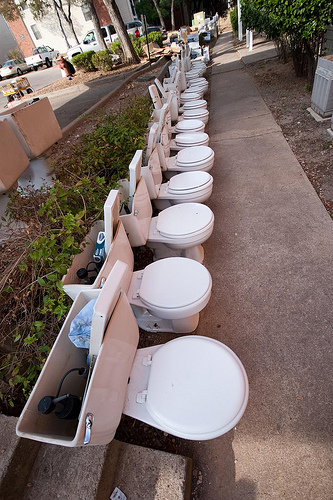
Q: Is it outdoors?
A: Yes, it is outdoors.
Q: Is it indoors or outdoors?
A: It is outdoors.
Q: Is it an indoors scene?
A: No, it is outdoors.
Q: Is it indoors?
A: No, it is outdoors.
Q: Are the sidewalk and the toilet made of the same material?
A: Yes, both the sidewalk and the toilet are made of concrete.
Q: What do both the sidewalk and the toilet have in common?
A: The material, both the sidewalk and the toilet are concrete.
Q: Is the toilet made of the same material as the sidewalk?
A: Yes, both the toilet and the sidewalk are made of concrete.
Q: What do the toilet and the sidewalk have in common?
A: The material, both the toilet and the sidewalk are concrete.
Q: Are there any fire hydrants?
A: Yes, there is a fire hydrant.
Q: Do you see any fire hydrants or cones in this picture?
A: Yes, there is a fire hydrant.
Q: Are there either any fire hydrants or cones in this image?
A: Yes, there is a fire hydrant.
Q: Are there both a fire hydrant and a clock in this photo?
A: No, there is a fire hydrant but no clocks.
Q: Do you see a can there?
A: No, there are no cans.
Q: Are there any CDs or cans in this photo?
A: No, there are no cans or cds.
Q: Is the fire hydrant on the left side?
A: Yes, the fire hydrant is on the left of the image.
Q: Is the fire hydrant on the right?
A: No, the fire hydrant is on the left of the image.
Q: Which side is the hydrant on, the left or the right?
A: The hydrant is on the left of the image.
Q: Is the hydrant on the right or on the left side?
A: The hydrant is on the left of the image.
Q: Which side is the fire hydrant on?
A: The fire hydrant is on the left of the image.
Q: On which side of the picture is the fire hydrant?
A: The fire hydrant is on the left of the image.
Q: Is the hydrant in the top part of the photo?
A: Yes, the hydrant is in the top of the image.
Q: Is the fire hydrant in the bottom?
A: No, the fire hydrant is in the top of the image.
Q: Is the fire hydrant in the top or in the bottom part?
A: The fire hydrant is in the top of the image.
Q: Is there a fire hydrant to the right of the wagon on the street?
A: Yes, there is a fire hydrant to the right of the wagon.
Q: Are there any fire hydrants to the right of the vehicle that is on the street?
A: Yes, there is a fire hydrant to the right of the wagon.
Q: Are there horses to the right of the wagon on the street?
A: No, there is a fire hydrant to the right of the wagon.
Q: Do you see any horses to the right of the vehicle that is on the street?
A: No, there is a fire hydrant to the right of the wagon.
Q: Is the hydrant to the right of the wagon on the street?
A: Yes, the hydrant is to the right of the wagon.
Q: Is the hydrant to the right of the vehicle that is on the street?
A: Yes, the hydrant is to the right of the wagon.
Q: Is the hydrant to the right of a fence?
A: No, the hydrant is to the right of the wagon.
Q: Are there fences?
A: No, there are no fences.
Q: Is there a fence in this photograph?
A: No, there are no fences.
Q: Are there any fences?
A: No, there are no fences.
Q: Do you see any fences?
A: No, there are no fences.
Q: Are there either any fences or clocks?
A: No, there are no fences or clocks.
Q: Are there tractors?
A: No, there are no tractors.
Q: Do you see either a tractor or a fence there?
A: No, there are no tractors or fences.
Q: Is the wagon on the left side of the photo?
A: Yes, the wagon is on the left of the image.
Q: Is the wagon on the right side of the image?
A: No, the wagon is on the left of the image.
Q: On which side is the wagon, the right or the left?
A: The wagon is on the left of the image.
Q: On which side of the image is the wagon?
A: The wagon is on the left of the image.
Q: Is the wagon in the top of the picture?
A: Yes, the wagon is in the top of the image.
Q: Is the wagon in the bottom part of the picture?
A: No, the wagon is in the top of the image.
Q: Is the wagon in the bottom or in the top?
A: The wagon is in the top of the image.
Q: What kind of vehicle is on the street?
A: The vehicle is a wagon.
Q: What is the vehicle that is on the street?
A: The vehicle is a wagon.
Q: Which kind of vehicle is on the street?
A: The vehicle is a wagon.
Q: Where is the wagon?
A: The wagon is on the street.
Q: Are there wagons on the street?
A: Yes, there is a wagon on the street.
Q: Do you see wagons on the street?
A: Yes, there is a wagon on the street.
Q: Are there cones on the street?
A: No, there is a wagon on the street.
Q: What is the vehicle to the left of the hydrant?
A: The vehicle is a wagon.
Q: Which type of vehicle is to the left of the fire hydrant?
A: The vehicle is a wagon.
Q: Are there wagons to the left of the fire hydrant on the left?
A: Yes, there is a wagon to the left of the hydrant.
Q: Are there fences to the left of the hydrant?
A: No, there is a wagon to the left of the hydrant.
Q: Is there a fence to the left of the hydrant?
A: No, there is a wagon to the left of the hydrant.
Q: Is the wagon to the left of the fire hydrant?
A: Yes, the wagon is to the left of the fire hydrant.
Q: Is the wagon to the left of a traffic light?
A: No, the wagon is to the left of the fire hydrant.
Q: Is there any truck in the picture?
A: Yes, there is a truck.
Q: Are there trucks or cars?
A: Yes, there is a truck.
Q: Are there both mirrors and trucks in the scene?
A: No, there is a truck but no mirrors.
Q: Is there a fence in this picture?
A: No, there are no fences.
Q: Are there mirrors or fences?
A: No, there are no fences or mirrors.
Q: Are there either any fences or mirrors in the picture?
A: No, there are no fences or mirrors.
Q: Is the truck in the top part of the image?
A: Yes, the truck is in the top of the image.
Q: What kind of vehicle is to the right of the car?
A: The vehicle is a truck.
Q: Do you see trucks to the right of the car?
A: Yes, there is a truck to the right of the car.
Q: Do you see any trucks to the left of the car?
A: No, the truck is to the right of the car.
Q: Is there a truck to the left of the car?
A: No, the truck is to the right of the car.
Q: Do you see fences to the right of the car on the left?
A: No, there is a truck to the right of the car.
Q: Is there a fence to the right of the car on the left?
A: No, there is a truck to the right of the car.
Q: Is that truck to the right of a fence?
A: No, the truck is to the right of the car.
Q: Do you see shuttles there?
A: No, there are no shuttles.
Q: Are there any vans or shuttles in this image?
A: No, there are no shuttles or vans.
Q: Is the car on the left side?
A: Yes, the car is on the left of the image.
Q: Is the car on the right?
A: No, the car is on the left of the image.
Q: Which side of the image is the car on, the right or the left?
A: The car is on the left of the image.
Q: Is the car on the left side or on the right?
A: The car is on the left of the image.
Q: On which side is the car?
A: The car is on the left of the image.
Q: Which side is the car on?
A: The car is on the left of the image.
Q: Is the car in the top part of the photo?
A: Yes, the car is in the top of the image.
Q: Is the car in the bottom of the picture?
A: No, the car is in the top of the image.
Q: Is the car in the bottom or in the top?
A: The car is in the top of the image.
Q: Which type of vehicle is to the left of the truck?
A: The vehicle is a car.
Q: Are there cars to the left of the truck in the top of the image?
A: Yes, there is a car to the left of the truck.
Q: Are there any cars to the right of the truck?
A: No, the car is to the left of the truck.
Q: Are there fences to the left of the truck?
A: No, there is a car to the left of the truck.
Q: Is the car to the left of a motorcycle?
A: No, the car is to the left of the truck.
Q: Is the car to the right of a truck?
A: No, the car is to the left of a truck.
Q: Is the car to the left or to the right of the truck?
A: The car is to the left of the truck.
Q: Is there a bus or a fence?
A: No, there are no fences or buses.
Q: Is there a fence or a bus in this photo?
A: No, there are no fences or buses.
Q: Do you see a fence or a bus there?
A: No, there are no fences or buses.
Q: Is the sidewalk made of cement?
A: Yes, the sidewalk is made of cement.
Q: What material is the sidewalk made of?
A: The sidewalk is made of cement.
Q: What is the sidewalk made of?
A: The sidewalk is made of concrete.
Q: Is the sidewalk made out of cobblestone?
A: No, the sidewalk is made of cement.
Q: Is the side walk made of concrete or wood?
A: The side walk is made of concrete.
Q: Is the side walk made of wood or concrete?
A: The side walk is made of concrete.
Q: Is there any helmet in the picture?
A: No, there are no helmets.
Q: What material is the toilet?
A: The toilet is made of cement.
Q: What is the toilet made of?
A: The toilet is made of concrete.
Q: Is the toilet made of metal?
A: No, the toilet is made of concrete.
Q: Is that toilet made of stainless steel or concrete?
A: The toilet is made of concrete.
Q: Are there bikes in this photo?
A: No, there are no bikes.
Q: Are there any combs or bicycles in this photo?
A: No, there are no bicycles or combs.